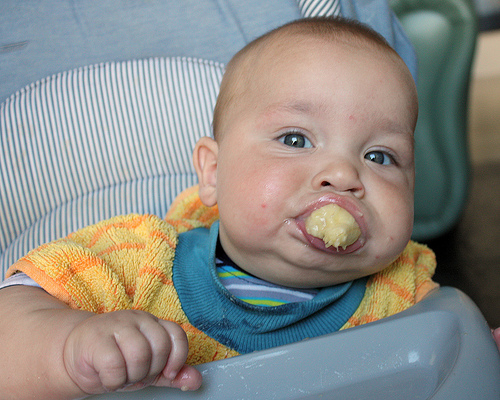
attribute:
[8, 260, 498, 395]
chair — high, blue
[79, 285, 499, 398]
object —  blue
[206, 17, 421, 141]
hair — short, trimmed, dark,  little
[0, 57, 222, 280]
cushion — light blue, white, high chair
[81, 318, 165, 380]
hand — little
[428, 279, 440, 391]
tray — plastic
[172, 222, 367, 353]
stretch neckline — blue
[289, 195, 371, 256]
mouth —   baby's,  open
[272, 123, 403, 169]
eyes — gray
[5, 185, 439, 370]
bib — blue, yellow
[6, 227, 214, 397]
arm — little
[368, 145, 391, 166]
left eye — baby's, beautiful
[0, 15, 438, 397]
baby — small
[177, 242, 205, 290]
collar — blue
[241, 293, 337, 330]
shirt — baby's, multicolored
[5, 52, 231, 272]
clothing — white , striped blue 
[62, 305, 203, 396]
hand —  baby's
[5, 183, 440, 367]
towel — yellow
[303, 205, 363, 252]
food —  yellow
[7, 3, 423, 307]
chair —  blue and white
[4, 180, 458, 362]
bib — terrycloth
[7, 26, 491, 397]
high chair — baby's